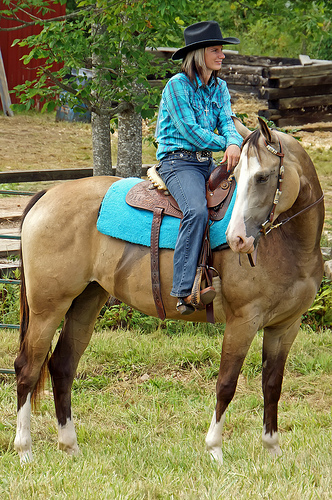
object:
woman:
[155, 20, 244, 316]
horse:
[13, 116, 325, 469]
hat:
[171, 20, 240, 60]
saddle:
[125, 161, 238, 223]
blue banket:
[97, 176, 240, 251]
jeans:
[156, 150, 208, 299]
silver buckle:
[196, 151, 209, 162]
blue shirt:
[155, 71, 243, 161]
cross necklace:
[204, 104, 210, 117]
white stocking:
[14, 406, 34, 466]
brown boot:
[176, 286, 217, 316]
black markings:
[262, 353, 286, 429]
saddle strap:
[209, 159, 234, 192]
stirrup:
[190, 246, 216, 312]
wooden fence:
[257, 63, 331, 124]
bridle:
[276, 177, 325, 237]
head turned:
[225, 116, 320, 255]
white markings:
[228, 147, 263, 239]